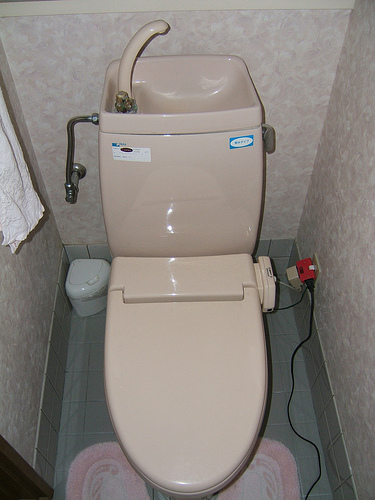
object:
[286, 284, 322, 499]
cord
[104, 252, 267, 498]
seat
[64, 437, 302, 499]
rug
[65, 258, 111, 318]
bin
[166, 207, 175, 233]
reflection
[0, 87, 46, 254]
towel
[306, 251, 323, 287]
outlet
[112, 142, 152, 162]
sticker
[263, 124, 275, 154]
flusher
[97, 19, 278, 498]
toilet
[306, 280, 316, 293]
plug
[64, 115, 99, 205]
plumbing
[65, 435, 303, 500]
carpet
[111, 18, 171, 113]
faucet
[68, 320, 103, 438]
floor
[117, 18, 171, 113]
fountain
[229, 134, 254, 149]
stickers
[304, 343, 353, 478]
tile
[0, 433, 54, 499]
door frame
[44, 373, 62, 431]
tile